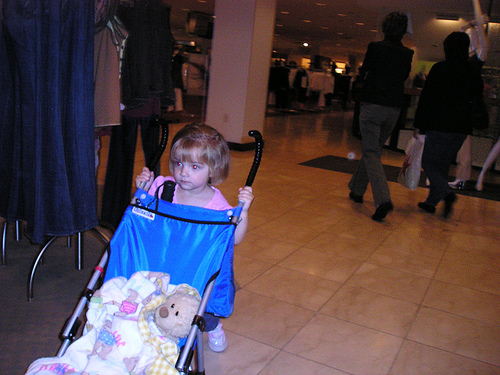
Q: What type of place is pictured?
A: It is a walkway.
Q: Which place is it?
A: It is a walkway.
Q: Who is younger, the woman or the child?
A: The child is younger than the woman.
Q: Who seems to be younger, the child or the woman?
A: The child is younger than the woman.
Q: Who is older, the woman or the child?
A: The woman is older than the child.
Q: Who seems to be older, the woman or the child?
A: The woman is older than the child.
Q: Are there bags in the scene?
A: Yes, there is a bag.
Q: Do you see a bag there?
A: Yes, there is a bag.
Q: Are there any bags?
A: Yes, there is a bag.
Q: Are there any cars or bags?
A: Yes, there is a bag.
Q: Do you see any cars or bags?
A: Yes, there is a bag.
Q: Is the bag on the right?
A: Yes, the bag is on the right of the image.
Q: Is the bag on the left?
A: No, the bag is on the right of the image.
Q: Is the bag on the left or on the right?
A: The bag is on the right of the image.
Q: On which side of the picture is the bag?
A: The bag is on the right of the image.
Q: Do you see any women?
A: Yes, there is a woman.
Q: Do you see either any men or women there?
A: Yes, there is a woman.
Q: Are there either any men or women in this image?
A: Yes, there is a woman.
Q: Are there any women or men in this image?
A: Yes, there is a woman.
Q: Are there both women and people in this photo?
A: Yes, there are both a woman and people.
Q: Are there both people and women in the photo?
A: Yes, there are both a woman and people.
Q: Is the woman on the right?
A: Yes, the woman is on the right of the image.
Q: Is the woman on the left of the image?
A: No, the woman is on the right of the image.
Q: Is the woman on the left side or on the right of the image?
A: The woman is on the right of the image.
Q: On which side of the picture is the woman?
A: The woman is on the right of the image.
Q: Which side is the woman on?
A: The woman is on the right of the image.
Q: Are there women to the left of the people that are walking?
A: Yes, there is a woman to the left of the people.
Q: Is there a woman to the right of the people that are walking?
A: No, the woman is to the left of the people.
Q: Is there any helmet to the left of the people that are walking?
A: No, there is a woman to the left of the people.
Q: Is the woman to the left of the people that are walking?
A: Yes, the woman is to the left of the people.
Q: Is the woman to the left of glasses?
A: No, the woman is to the left of the people.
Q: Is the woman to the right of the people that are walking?
A: No, the woman is to the left of the people.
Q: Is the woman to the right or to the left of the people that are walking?
A: The woman is to the left of the people.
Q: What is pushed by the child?
A: The stroller is pushed by the child.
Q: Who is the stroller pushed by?
A: The stroller is pushed by the kid.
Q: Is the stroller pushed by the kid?
A: Yes, the stroller is pushed by the kid.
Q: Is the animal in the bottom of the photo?
A: Yes, the animal is in the bottom of the image.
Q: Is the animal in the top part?
A: No, the animal is in the bottom of the image.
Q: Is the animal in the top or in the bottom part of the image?
A: The animal is in the bottom of the image.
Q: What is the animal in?
A: The animal is in the stroller.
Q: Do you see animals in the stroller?
A: Yes, there is an animal in the stroller.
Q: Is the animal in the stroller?
A: Yes, the animal is in the stroller.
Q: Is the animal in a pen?
A: No, the animal is in the stroller.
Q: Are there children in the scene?
A: Yes, there is a child.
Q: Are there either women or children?
A: Yes, there is a child.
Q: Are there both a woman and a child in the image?
A: Yes, there are both a child and a woman.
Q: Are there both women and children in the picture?
A: Yes, there are both a child and a woman.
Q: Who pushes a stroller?
A: The kid pushes a stroller.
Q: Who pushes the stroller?
A: The kid pushes a stroller.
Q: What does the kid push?
A: The kid pushes a stroller.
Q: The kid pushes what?
A: The kid pushes a stroller.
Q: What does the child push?
A: The kid pushes a stroller.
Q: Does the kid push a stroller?
A: Yes, the kid pushes a stroller.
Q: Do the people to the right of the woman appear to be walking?
A: Yes, the people are walking.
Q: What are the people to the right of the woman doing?
A: The people are walking.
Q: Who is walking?
A: The people are walking.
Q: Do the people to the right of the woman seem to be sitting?
A: No, the people are walking.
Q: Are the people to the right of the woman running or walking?
A: The people are walking.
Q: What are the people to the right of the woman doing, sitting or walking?
A: The people are walking.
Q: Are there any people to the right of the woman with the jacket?
A: Yes, there are people to the right of the woman.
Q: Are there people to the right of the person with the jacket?
A: Yes, there are people to the right of the woman.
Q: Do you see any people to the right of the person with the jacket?
A: Yes, there are people to the right of the woman.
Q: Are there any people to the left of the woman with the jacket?
A: No, the people are to the right of the woman.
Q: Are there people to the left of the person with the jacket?
A: No, the people are to the right of the woman.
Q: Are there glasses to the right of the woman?
A: No, there are people to the right of the woman.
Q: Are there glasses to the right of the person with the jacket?
A: No, there are people to the right of the woman.